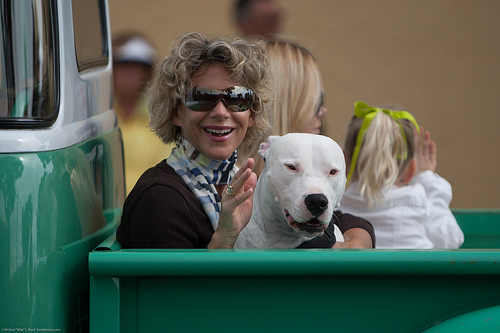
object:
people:
[108, 29, 376, 254]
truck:
[0, 0, 500, 333]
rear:
[90, 198, 500, 330]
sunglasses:
[176, 84, 257, 113]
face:
[175, 63, 255, 155]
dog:
[226, 130, 354, 253]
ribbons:
[345, 103, 425, 185]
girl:
[341, 100, 471, 257]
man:
[222, 0, 290, 41]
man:
[108, 34, 178, 198]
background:
[114, 0, 499, 209]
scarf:
[161, 136, 241, 232]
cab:
[3, 1, 128, 332]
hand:
[212, 155, 259, 235]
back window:
[68, 0, 114, 73]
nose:
[305, 194, 327, 218]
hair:
[143, 41, 272, 146]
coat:
[334, 167, 467, 252]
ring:
[224, 183, 239, 197]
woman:
[227, 31, 327, 174]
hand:
[414, 127, 439, 178]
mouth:
[279, 203, 333, 236]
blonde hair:
[237, 31, 319, 177]